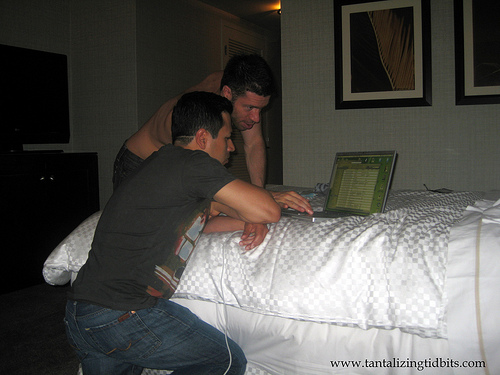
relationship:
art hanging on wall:
[334, 0, 433, 113] [275, 5, 498, 211]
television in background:
[2, 44, 81, 150] [3, 5, 284, 373]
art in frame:
[327, 0, 441, 116] [326, 6, 434, 114]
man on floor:
[61, 84, 284, 374] [11, 285, 499, 371]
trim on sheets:
[464, 217, 499, 372] [43, 193, 499, 372]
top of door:
[232, 15, 285, 58] [244, 15, 287, 204]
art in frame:
[334, 0, 433, 113] [324, 0, 442, 115]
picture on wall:
[451, 6, 499, 107] [275, 5, 498, 211]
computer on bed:
[297, 142, 401, 226] [32, 169, 499, 371]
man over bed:
[110, 45, 289, 219] [32, 169, 499, 371]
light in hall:
[268, 5, 288, 26] [226, 5, 286, 234]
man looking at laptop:
[61, 84, 284, 374] [277, 139, 401, 229]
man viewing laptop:
[61, 84, 284, 374] [283, 145, 403, 225]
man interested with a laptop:
[128, 84, 277, 234] [301, 137, 422, 238]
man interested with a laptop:
[110, 52, 315, 218] [301, 137, 422, 238]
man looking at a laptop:
[110, 52, 315, 218] [292, 139, 417, 251]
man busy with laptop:
[110, 52, 315, 218] [301, 144, 401, 234]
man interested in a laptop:
[110, 52, 315, 218] [301, 139, 406, 237]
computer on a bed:
[281, 149, 400, 226] [176, 133, 497, 353]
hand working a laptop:
[261, 188, 316, 217] [307, 139, 401, 224]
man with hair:
[110, 52, 315, 218] [234, 55, 283, 104]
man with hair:
[110, 52, 315, 218] [236, 62, 296, 114]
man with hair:
[61, 84, 284, 374] [172, 77, 217, 127]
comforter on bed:
[285, 208, 419, 335] [176, 131, 394, 358]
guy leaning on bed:
[150, 88, 259, 204] [101, 180, 499, 350]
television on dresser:
[2, 44, 81, 150] [1, 133, 150, 363]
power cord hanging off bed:
[201, 230, 248, 371] [112, 171, 468, 372]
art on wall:
[334, 0, 433, 113] [276, 8, 486, 229]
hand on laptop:
[261, 188, 328, 235] [294, 137, 404, 227]